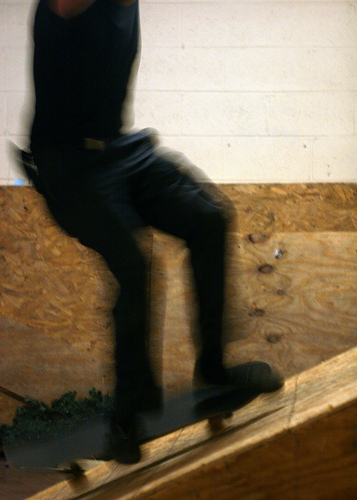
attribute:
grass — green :
[3, 385, 116, 454]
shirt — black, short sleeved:
[23, 0, 140, 144]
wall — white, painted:
[195, 0, 353, 186]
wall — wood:
[0, 183, 354, 428]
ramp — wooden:
[38, 347, 355, 498]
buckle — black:
[80, 135, 109, 156]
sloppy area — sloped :
[285, 352, 344, 454]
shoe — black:
[220, 359, 284, 390]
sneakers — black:
[109, 143, 305, 391]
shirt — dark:
[28, 0, 145, 150]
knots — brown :
[241, 228, 284, 345]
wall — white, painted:
[0, 0, 355, 185]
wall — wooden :
[209, 37, 355, 336]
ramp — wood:
[303, 363, 348, 408]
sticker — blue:
[9, 175, 32, 190]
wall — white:
[2, 88, 49, 191]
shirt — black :
[20, 2, 145, 156]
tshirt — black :
[28, 16, 136, 130]